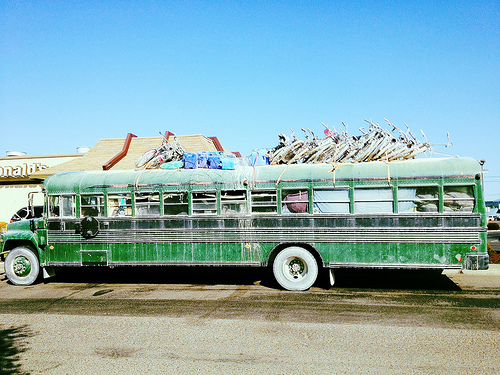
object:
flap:
[329, 268, 335, 286]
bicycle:
[264, 130, 288, 165]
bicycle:
[269, 127, 297, 164]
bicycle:
[312, 123, 332, 163]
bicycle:
[359, 118, 389, 163]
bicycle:
[395, 121, 417, 159]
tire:
[4, 246, 39, 285]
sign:
[78, 216, 99, 239]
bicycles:
[398, 121, 452, 160]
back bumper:
[466, 254, 489, 270]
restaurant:
[1, 132, 243, 219]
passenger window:
[80, 194, 105, 218]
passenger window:
[134, 191, 161, 216]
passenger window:
[163, 192, 188, 215]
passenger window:
[220, 190, 248, 214]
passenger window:
[313, 189, 349, 213]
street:
[1, 269, 498, 373]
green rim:
[12, 255, 31, 277]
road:
[1, 270, 498, 373]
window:
[51, 197, 73, 217]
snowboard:
[272, 246, 319, 292]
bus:
[0, 156, 490, 291]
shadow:
[1, 323, 41, 375]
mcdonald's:
[0, 130, 226, 218]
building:
[0, 151, 47, 224]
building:
[28, 131, 243, 208]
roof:
[42, 156, 490, 192]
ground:
[2, 309, 92, 373]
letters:
[0, 160, 50, 176]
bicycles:
[135, 130, 186, 171]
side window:
[28, 191, 46, 216]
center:
[286, 258, 304, 279]